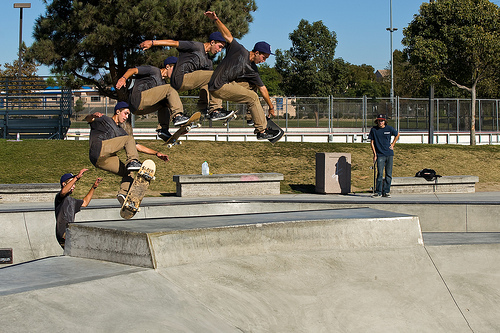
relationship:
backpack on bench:
[417, 161, 432, 187] [373, 166, 475, 198]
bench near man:
[373, 166, 475, 198] [369, 113, 396, 191]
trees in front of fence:
[17, 0, 273, 118] [11, 86, 498, 156]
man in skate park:
[366, 113, 400, 198] [9, 134, 493, 331]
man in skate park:
[53, 167, 101, 248] [9, 134, 493, 331]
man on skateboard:
[370, 114, 399, 198] [370, 149, 380, 194]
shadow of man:
[332, 149, 359, 203] [361, 110, 401, 199]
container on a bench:
[201, 158, 209, 175] [171, 170, 284, 198]